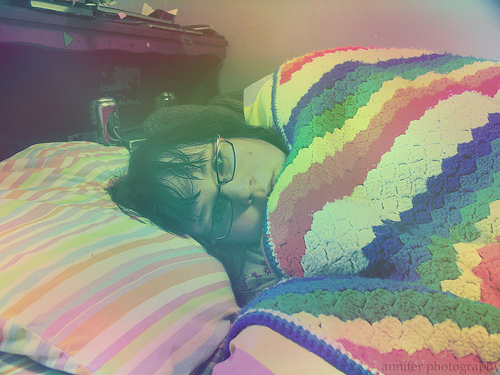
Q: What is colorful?
A: Blanket.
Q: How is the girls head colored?
A: Brown.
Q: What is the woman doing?
A: Laying.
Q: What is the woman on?
A: A bed.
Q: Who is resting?
A: A girl.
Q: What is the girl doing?
A: Resting.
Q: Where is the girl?
A: In bed.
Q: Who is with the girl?
A: No people.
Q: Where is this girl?
A: In bed.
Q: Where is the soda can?
A: On the headboard.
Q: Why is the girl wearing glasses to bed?
A: For the pose.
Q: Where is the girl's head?
A: On a stripped pillow.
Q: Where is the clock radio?
A: On the headboard.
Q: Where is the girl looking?
A: At the photographer.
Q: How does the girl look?
A: Tired.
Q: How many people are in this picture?
A: One.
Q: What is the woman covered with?
A: An afghan.